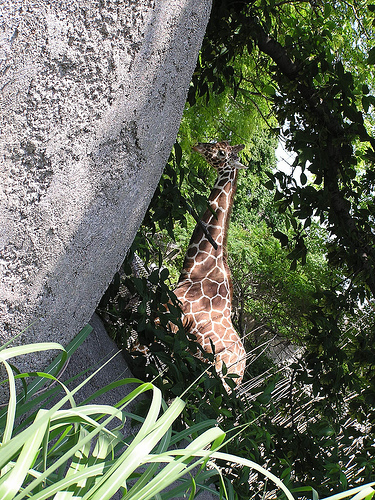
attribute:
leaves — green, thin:
[262, 123, 347, 274]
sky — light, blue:
[278, 143, 317, 184]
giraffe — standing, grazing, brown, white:
[166, 134, 273, 394]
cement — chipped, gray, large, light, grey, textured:
[2, 0, 214, 395]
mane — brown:
[225, 172, 241, 280]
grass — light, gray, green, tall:
[0, 338, 276, 498]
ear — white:
[229, 157, 248, 172]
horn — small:
[232, 149, 244, 161]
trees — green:
[278, 50, 368, 242]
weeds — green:
[2, 293, 374, 496]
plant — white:
[238, 332, 365, 474]